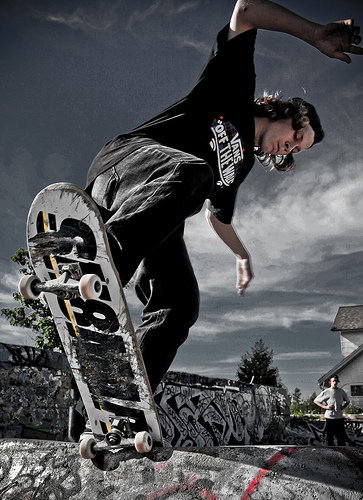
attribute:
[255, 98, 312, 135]
hair — long, curly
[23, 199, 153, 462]
skateboard — four, white, black, used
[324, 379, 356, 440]
man — standing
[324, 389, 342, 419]
shirt — gray, white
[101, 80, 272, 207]
shirt — black, vans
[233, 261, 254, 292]
hand — human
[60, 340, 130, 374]
letter — written, black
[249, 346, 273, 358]
needles — green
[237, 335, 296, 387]
tree — pine, lush, green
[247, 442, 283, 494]
line — red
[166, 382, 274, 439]
graffiti — black, white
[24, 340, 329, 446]
wall — retaining, concrete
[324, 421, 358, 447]
jeans — black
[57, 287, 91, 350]
line — yellow, black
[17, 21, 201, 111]
sky — gray, cloudy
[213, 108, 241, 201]
letters — white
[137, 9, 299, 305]
guy — about to fall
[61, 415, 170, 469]
wheels — rear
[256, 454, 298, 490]
paint — red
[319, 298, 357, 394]
home — two story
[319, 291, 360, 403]
house — white, two story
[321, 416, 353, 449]
pants — black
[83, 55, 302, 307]
man — young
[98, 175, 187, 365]
jeans — black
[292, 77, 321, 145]
hat — black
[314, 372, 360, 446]
guy — standing